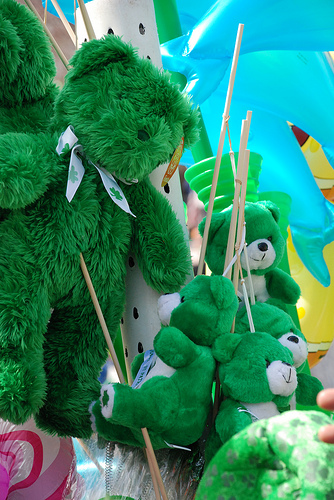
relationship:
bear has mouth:
[22, 73, 144, 374] [93, 139, 170, 189]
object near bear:
[115, 12, 206, 339] [22, 73, 144, 374]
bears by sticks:
[159, 194, 323, 444] [182, 63, 283, 324]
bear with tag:
[22, 73, 144, 374] [84, 172, 152, 212]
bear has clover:
[156, 262, 226, 446] [95, 383, 141, 418]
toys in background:
[164, 16, 328, 143] [140, 17, 314, 94]